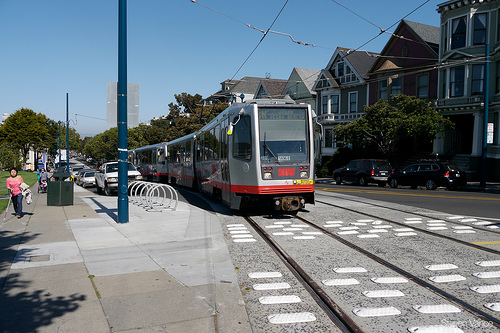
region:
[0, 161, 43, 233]
Woman walking with cane.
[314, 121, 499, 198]
Cars parked along road.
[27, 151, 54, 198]
Person in wheelchair going down sidewalk.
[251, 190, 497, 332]
Two sets of train tracks.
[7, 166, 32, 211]
woman walking down sidewalk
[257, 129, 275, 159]
windshield wiper on train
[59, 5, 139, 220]
blue utility poles on the sidewalk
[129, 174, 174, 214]
bike rack on the sidewalk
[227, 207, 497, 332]
white rectangles on the road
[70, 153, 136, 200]
cars parked beside the sidewalk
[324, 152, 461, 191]
cars parked in front of houses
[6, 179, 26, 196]
pink shirt of woman walking down sidewalk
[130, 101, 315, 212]
train stopped on it's tracks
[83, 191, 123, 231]
shadow of pole on sidewalk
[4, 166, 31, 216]
woman in a pink shirt and a cane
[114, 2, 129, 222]
tall blue pole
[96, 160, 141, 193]
white truck parked at the curb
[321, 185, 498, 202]
painted yellow line on the street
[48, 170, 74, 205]
large green garbage can on the sidewalk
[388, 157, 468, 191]
parked black car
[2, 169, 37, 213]
section of green grass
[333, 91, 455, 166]
tree in front of the houses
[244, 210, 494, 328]
metal train tracks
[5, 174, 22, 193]
The pink shirt the lady is wearing.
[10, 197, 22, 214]
The blue jeans the lady is wearing.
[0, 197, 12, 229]
The walking stick the lady is using.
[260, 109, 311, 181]
The front window of the trolley.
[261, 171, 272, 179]
The left headlight of the trolley.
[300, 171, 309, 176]
The right headlight of the trolley.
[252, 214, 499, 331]
The tracks the trolley is driving on.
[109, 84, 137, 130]
The back of the sign on the blue pole.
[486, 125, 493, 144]
The signs on the blue pole on the right.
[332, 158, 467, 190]
The two black vehicles parked on the right.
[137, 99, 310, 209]
train stopped at a train stop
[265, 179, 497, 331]
train tracks in the road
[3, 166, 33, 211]
woman wearing pink shirt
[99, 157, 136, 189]
white truck parked on street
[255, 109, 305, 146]
front window on train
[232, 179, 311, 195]
red bumper on train car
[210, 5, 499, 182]
row of houses next to tracks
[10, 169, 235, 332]
sidewalk next to train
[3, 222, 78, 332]
shadows on the sidewalk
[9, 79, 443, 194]
trees along the street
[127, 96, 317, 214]
Commuter train on the track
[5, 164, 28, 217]
Woman walking on the sidewalk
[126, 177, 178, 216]
Empty bicycle rack on the sidewalk